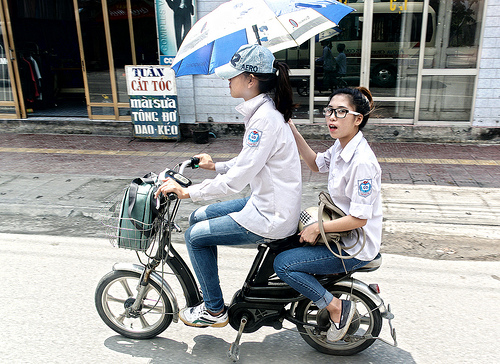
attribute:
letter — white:
[131, 108, 158, 121]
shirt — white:
[217, 120, 304, 242]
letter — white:
[135, 97, 177, 137]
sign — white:
[122, 62, 180, 140]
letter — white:
[133, 67, 140, 76]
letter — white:
[153, 65, 165, 77]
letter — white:
[145, 63, 157, 79]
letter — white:
[126, 95, 143, 110]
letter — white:
[128, 110, 138, 124]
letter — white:
[135, 111, 145, 118]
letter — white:
[140, 127, 147, 134]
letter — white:
[156, 126, 168, 139]